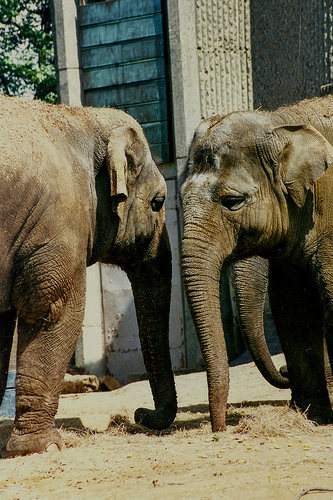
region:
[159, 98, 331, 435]
elephant standing in the field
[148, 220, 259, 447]
trunk of the elephant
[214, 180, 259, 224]
elephant has black eye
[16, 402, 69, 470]
elephant has gray feet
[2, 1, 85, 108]
tree behind the elephant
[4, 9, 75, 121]
tree has green leaves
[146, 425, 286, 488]
the hay is yellow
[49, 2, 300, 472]
building next to the elephants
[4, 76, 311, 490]
elephants looking at each other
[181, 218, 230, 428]
Long gray elephant trunk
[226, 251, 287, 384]
Curved gray elephant trunk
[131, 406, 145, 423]
Tip of elephant's trunk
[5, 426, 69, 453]
Elephant's foot on the ground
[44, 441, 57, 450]
Elephant toe on foot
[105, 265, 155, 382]
Metal door to enclosure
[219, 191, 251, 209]
Large eye in elephant's head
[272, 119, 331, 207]
Ear on elephant's head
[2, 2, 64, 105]
Tree with green leaves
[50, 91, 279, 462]
two elephants facing each other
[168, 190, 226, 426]
lines on elephant's trunk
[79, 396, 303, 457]
dry hay on the ground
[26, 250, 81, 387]
elephant's skin is wrinkled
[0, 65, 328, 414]
elephants facing each other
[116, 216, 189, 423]
the trunk is long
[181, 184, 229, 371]
the skin is wrinkled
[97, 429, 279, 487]
the dirt is light brown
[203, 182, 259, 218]
the eye is open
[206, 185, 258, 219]
the eye is black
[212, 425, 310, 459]
pellets on the dirt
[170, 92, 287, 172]
the head is a little hairy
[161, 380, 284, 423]
shadow on the ground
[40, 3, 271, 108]
a building in the background